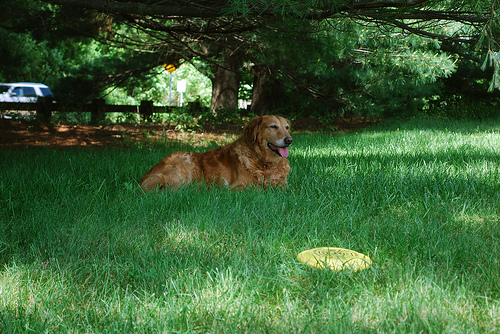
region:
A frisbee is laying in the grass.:
[278, 230, 390, 287]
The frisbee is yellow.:
[286, 232, 398, 294]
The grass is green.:
[138, 235, 266, 313]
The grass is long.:
[131, 218, 288, 311]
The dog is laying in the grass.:
[137, 107, 304, 202]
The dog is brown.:
[139, 105, 309, 207]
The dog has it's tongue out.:
[134, 110, 309, 205]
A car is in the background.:
[1, 71, 66, 126]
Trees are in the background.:
[185, 7, 435, 104]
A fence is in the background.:
[1, 90, 215, 125]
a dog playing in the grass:
[16, 20, 458, 308]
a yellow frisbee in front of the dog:
[123, 91, 393, 309]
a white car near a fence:
[3, 61, 84, 144]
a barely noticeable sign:
[141, 48, 198, 86]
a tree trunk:
[128, 4, 306, 129]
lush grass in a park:
[43, 156, 498, 321]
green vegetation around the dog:
[224, 13, 484, 120]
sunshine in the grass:
[11, 201, 473, 331]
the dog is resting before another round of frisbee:
[128, 105, 393, 282]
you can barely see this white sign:
[163, 77, 218, 128]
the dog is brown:
[118, 89, 385, 212]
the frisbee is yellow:
[284, 212, 399, 296]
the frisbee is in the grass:
[180, 193, 460, 318]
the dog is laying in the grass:
[102, 103, 370, 213]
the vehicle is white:
[1, 68, 57, 145]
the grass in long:
[13, 121, 498, 285]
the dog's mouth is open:
[215, 96, 313, 188]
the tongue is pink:
[263, 130, 300, 176]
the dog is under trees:
[9, 1, 452, 253]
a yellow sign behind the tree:
[154, 51, 202, 96]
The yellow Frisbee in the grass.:
[292, 235, 384, 281]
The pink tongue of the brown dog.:
[275, 143, 292, 158]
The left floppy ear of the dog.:
[248, 111, 261, 143]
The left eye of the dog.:
[266, 121, 278, 131]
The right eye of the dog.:
[281, 121, 292, 130]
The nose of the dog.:
[284, 134, 293, 144]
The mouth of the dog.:
[267, 139, 290, 156]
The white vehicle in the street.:
[1, 78, 55, 118]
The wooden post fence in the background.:
[3, 86, 275, 127]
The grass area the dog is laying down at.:
[92, 128, 406, 232]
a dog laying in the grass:
[77, 70, 412, 235]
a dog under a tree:
[86, 32, 376, 255]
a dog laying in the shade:
[62, 17, 364, 238]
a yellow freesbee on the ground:
[307, 196, 444, 306]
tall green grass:
[14, 173, 232, 310]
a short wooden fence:
[10, 59, 215, 141]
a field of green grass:
[328, 131, 496, 252]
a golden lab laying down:
[127, 66, 358, 227]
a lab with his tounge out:
[68, 82, 362, 202]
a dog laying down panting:
[74, 82, 353, 231]